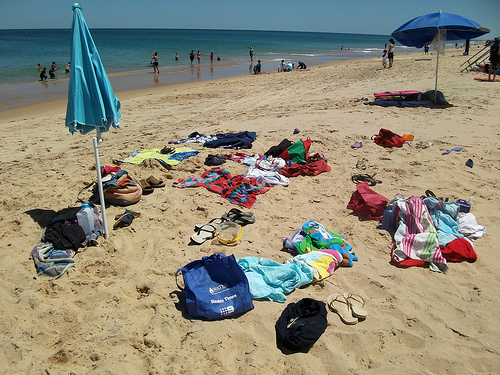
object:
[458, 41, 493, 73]
stairs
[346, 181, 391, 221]
bag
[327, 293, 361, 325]
shoes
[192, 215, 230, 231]
shoes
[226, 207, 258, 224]
shoes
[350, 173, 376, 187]
shoes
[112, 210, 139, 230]
shoes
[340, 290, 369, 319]
slipper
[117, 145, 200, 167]
beach towel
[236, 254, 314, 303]
cloth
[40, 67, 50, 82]
people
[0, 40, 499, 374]
sand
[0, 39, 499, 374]
ground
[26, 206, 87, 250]
belonging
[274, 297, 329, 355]
belonging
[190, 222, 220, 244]
belonging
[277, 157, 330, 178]
belonging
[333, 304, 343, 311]
side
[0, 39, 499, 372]
beach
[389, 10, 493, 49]
umbrella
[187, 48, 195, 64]
people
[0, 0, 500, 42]
sky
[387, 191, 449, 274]
towel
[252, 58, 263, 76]
visitor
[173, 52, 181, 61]
visitor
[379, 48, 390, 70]
visitor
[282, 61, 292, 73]
visitor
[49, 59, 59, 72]
visitor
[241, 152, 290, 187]
belongings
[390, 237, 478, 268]
belongings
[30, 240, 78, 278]
belongings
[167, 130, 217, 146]
belongings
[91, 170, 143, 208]
belongings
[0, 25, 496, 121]
shore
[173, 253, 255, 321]
bag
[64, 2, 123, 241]
umbrella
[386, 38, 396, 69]
people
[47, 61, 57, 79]
people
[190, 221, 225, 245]
flip flop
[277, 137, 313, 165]
bag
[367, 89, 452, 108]
chair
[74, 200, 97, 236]
water jug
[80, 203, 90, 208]
cap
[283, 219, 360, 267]
clothes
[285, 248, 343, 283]
clothes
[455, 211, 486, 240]
clothes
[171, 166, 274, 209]
clothes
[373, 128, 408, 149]
clothes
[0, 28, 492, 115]
ocean